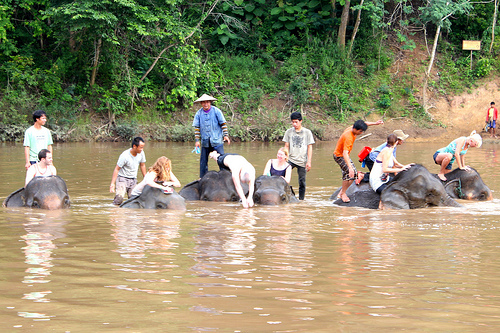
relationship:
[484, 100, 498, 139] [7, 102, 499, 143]
kid standing on shore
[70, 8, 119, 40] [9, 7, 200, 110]
leaves are covering trees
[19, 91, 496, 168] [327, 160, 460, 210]
people are riding elephant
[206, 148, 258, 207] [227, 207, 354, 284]
man diving into water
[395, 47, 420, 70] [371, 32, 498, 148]
dirt on dirt-covered hillside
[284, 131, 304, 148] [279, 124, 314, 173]
design on shirt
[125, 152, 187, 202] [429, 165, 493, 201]
girl riding elephant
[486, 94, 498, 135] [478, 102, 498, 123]
kid in jacket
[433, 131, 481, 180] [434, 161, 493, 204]
girl on elephant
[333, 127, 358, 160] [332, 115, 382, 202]
orange shirt on guy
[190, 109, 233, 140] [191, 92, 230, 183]
blue shirt on people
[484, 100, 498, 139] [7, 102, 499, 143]
kid on shore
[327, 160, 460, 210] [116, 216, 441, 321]
elephant in water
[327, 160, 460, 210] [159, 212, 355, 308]
elephant in water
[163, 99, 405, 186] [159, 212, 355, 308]
people in water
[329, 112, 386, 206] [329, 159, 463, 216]
boy on elephant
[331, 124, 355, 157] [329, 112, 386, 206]
orange shirt on boy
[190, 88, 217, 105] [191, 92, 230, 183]
hat on people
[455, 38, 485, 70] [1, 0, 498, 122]
sign by trees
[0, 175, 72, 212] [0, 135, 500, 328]
elephant in river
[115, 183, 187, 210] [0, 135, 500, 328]
elephant in river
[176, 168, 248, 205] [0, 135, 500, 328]
elephant in river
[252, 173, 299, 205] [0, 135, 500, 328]
elephant in river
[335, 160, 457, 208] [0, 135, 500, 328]
elephant in river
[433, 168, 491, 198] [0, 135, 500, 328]
elephant in river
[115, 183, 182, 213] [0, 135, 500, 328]
elephant in river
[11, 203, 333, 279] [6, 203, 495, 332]
reflection on water